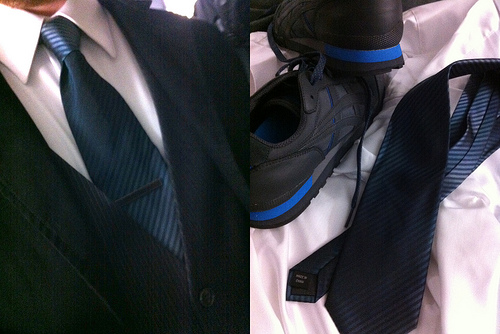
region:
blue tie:
[40, 23, 192, 260]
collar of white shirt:
[3, 8, 123, 75]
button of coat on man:
[201, 293, 219, 303]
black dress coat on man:
[4, 12, 246, 332]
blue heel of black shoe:
[247, 176, 315, 224]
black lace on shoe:
[292, 52, 325, 77]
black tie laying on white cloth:
[291, 58, 496, 329]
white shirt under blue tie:
[14, 45, 175, 190]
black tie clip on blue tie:
[114, 180, 164, 205]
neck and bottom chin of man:
[0, 0, 68, 15]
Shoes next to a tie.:
[240, 12, 435, 296]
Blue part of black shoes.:
[197, 131, 319, 224]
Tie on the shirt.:
[298, 48, 498, 332]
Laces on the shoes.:
[281, 35, 395, 136]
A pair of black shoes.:
[245, 0, 438, 250]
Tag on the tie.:
[257, 255, 367, 316]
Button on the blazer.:
[180, 263, 238, 331]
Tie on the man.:
[20, 7, 237, 275]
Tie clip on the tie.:
[24, 128, 258, 278]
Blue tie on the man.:
[27, 20, 157, 262]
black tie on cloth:
[282, 58, 494, 331]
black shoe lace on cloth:
[349, 88, 380, 225]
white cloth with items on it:
[262, 33, 489, 330]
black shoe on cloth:
[247, 58, 390, 221]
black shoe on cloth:
[268, 8, 402, 72]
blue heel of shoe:
[320, 43, 407, 61]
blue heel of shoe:
[255, 172, 317, 222]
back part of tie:
[282, 79, 496, 305]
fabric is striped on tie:
[328, 82, 452, 332]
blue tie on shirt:
[32, 33, 185, 253]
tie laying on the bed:
[284, 58, 499, 331]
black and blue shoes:
[248, 1, 415, 230]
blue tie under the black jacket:
[33, 14, 193, 269]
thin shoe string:
[340, 126, 367, 233]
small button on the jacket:
[194, 284, 218, 307]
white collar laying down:
[1, 2, 133, 84]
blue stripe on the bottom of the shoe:
[312, 41, 417, 71]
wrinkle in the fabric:
[403, 2, 494, 62]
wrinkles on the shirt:
[26, 46, 64, 133]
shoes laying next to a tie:
[247, 4, 498, 332]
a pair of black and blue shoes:
[247, 0, 407, 235]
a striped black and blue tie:
[270, 71, 499, 326]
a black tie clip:
[101, 165, 177, 227]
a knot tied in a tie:
[32, 16, 86, 82]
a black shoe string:
[337, 133, 381, 223]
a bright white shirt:
[424, 219, 499, 316]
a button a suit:
[184, 279, 222, 316]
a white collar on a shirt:
[12, 11, 42, 109]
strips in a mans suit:
[87, 222, 144, 278]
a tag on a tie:
[290, 273, 315, 290]